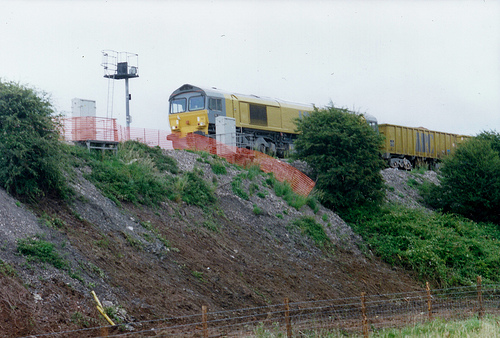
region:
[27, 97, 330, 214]
orange protective fence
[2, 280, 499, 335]
wood and wire fence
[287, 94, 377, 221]
dark green tree next to a train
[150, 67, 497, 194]
yellow and gray train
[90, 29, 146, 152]
a tower next to the train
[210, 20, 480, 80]
a gray sky above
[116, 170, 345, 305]
dirt and rocks on a hill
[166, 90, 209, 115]
windshield of the train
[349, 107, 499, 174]
box car on a train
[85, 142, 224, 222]
weeds growing into bushes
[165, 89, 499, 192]
Long yellow train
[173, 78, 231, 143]
Front little section of train is grey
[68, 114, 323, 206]
Orange fence coming down hill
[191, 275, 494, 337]
Wire and stick fence at the bottom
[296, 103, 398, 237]
Large bush next to train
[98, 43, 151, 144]
A pole with an area to stand on top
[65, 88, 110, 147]
Some kind of electrical box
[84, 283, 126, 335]
Yellow stick on the ground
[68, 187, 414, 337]
Dark brown dirt on hill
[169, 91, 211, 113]
Two windows on front of train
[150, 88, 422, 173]
the train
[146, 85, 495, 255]
the train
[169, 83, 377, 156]
a yellow and grey train engine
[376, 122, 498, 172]
a yellow and grey train car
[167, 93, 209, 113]
windshield of a train engine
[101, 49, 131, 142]
watch tower in a train yard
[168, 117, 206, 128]
headlights of a train engine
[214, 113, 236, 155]
metal electrical box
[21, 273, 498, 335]
a wire fence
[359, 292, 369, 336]
a wooden fence post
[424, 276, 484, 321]
two wooden fence posts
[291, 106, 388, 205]
tree on a slope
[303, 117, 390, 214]
a large green bush by a train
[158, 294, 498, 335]
a wire fence at the bottom of a hill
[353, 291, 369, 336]
a wooden post in the middle of the fence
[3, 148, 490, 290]
a dirt hill beside a railroad track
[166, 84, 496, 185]
a yellow train on tracks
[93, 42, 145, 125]
an observation tower behind a train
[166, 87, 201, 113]
the front windshield of the train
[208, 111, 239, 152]
a white container beside the tracks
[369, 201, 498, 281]
a clump of growing grass on the hillside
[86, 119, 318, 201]
a broken red fence hanging down the hillside